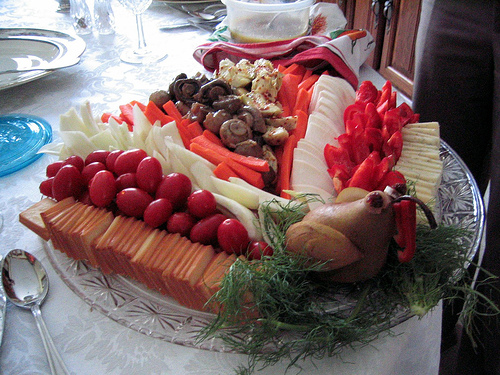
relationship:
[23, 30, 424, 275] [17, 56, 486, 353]
food on foodplatter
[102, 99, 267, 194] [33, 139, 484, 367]
raw carrots on platter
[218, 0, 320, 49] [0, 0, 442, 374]
bowl on table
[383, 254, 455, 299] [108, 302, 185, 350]
dill herb on platter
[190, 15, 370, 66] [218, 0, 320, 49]
cloth under bowl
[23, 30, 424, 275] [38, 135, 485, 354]
food on plate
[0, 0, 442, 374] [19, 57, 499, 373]
table filled with food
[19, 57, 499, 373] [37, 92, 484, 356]
food and plate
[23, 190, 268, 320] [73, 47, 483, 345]
cheese on plate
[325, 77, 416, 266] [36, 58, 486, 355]
red peppers are on plate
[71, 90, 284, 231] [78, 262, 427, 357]
sliced vegetables are on plate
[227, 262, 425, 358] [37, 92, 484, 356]
garnish in on plate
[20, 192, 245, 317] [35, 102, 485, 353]
cheese on platter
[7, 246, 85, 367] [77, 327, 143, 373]
silver spoon on table cloth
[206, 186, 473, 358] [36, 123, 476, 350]
garnish on platter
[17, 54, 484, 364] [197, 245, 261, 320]
platter with cheese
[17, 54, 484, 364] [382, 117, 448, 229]
platter with cheese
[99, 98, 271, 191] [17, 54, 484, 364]
carrots on platter